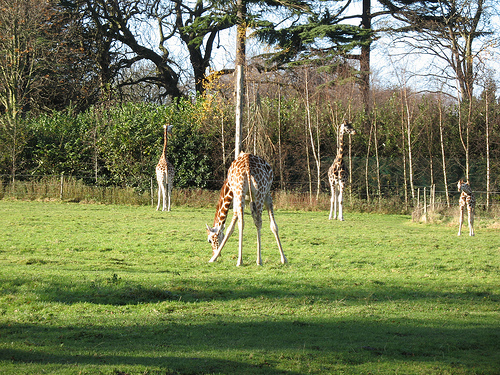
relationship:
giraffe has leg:
[196, 139, 289, 278] [233, 213, 252, 280]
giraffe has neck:
[196, 139, 289, 278] [217, 185, 234, 231]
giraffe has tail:
[196, 139, 289, 278] [242, 172, 264, 219]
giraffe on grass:
[196, 139, 289, 278] [65, 240, 494, 352]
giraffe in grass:
[196, 139, 289, 278] [65, 240, 494, 352]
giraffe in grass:
[445, 179, 481, 248] [65, 240, 494, 352]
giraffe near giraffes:
[445, 179, 481, 248] [139, 118, 479, 257]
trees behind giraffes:
[119, 18, 458, 141] [139, 118, 479, 257]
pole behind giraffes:
[230, 65, 249, 154] [139, 118, 479, 257]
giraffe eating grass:
[196, 139, 289, 278] [65, 240, 494, 352]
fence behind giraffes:
[42, 165, 417, 225] [139, 118, 479, 257]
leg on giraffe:
[233, 213, 252, 280] [196, 139, 289, 278]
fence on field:
[42, 165, 417, 225] [19, 175, 475, 374]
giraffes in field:
[139, 118, 479, 257] [19, 175, 475, 374]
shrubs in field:
[367, 103, 489, 189] [19, 175, 475, 374]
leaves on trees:
[280, 28, 322, 43] [119, 18, 458, 141]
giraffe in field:
[196, 139, 289, 278] [19, 175, 475, 374]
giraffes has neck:
[139, 118, 479, 257] [217, 185, 234, 231]